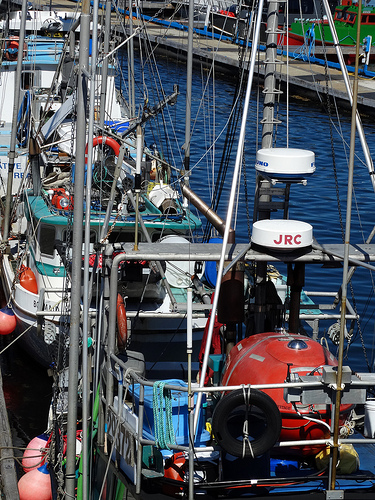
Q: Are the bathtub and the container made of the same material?
A: Yes, both the bathtub and the container are made of plastic.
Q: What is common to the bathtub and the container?
A: The material, both the bathtub and the container are plastic.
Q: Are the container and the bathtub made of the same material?
A: Yes, both the container and the bathtub are made of plastic.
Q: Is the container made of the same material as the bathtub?
A: Yes, both the container and the bathtub are made of plastic.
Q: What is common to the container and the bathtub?
A: The material, both the container and the bathtub are plastic.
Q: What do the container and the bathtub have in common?
A: The material, both the container and the bathtub are plastic.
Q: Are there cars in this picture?
A: No, there are no cars.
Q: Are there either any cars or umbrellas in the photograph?
A: No, there are no cars or umbrellas.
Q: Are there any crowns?
A: No, there are no crowns.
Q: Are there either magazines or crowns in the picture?
A: No, there are no crowns or magazines.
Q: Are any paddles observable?
A: No, there are no paddles.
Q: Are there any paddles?
A: No, there are no paddles.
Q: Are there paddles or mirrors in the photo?
A: No, there are no paddles or mirrors.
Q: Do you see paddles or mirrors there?
A: No, there are no paddles or mirrors.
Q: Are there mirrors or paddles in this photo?
A: No, there are no paddles or mirrors.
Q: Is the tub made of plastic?
A: Yes, the tub is made of plastic.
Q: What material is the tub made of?
A: The tub is made of plastic.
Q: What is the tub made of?
A: The tub is made of plastic.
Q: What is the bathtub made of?
A: The tub is made of plastic.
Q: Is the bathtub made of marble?
A: No, the bathtub is made of plastic.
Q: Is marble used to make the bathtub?
A: No, the bathtub is made of plastic.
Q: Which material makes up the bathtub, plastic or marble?
A: The bathtub is made of plastic.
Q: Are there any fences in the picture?
A: No, there are no fences.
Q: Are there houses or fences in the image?
A: No, there are no fences or houses.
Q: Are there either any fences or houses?
A: No, there are no fences or houses.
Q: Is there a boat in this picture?
A: Yes, there is a boat.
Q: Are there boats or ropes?
A: Yes, there is a boat.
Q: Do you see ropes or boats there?
A: Yes, there is a boat.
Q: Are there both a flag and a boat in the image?
A: No, there is a boat but no flags.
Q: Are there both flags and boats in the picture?
A: No, there is a boat but no flags.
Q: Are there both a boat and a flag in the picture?
A: No, there is a boat but no flags.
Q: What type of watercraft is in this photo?
A: The watercraft is a boat.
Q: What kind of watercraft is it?
A: The watercraft is a boat.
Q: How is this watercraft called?
A: This is a boat.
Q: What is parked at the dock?
A: The boat is parked at the dock.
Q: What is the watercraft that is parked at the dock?
A: The watercraft is a boat.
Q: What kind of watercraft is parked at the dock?
A: The watercraft is a boat.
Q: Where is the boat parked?
A: The boat is parked at the pier.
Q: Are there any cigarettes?
A: No, there are no cigarettes.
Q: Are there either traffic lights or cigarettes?
A: No, there are no cigarettes or traffic lights.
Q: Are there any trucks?
A: No, there are no trucks.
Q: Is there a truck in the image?
A: No, there are no trucks.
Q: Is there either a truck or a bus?
A: No, there are no trucks or buses.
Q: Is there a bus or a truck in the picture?
A: No, there are no trucks or buses.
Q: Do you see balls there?
A: Yes, there is a ball.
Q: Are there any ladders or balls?
A: Yes, there is a ball.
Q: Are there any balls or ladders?
A: Yes, there is a ball.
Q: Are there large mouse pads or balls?
A: Yes, there is a large ball.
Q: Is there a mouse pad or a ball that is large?
A: Yes, the ball is large.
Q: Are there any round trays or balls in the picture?
A: Yes, there is a round ball.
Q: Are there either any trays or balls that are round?
A: Yes, the ball is round.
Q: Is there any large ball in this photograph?
A: Yes, there is a large ball.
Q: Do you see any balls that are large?
A: Yes, there is a ball that is large.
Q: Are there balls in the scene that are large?
A: Yes, there is a ball that is large.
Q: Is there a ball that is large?
A: Yes, there is a ball that is large.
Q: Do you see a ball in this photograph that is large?
A: Yes, there is a ball that is large.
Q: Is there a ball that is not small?
A: Yes, there is a large ball.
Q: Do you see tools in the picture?
A: No, there are no tools.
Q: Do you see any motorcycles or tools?
A: No, there are no tools or motorcycles.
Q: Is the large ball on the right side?
A: Yes, the ball is on the right of the image.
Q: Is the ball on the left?
A: No, the ball is on the right of the image.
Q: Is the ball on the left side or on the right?
A: The ball is on the right of the image.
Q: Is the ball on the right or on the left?
A: The ball is on the right of the image.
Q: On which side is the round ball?
A: The ball is on the right of the image.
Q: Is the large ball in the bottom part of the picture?
A: Yes, the ball is in the bottom of the image.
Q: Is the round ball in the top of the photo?
A: No, the ball is in the bottom of the image.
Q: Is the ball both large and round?
A: Yes, the ball is large and round.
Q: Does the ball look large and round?
A: Yes, the ball is large and round.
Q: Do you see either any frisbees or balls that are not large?
A: No, there is a ball but it is large.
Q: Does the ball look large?
A: Yes, the ball is large.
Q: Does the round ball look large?
A: Yes, the ball is large.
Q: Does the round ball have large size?
A: Yes, the ball is large.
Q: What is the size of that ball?
A: The ball is large.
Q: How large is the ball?
A: The ball is large.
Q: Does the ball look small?
A: No, the ball is large.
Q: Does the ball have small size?
A: No, the ball is large.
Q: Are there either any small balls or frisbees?
A: No, there is a ball but it is large.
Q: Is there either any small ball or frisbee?
A: No, there is a ball but it is large.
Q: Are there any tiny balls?
A: No, there is a ball but it is large.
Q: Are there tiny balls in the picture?
A: No, there is a ball but it is large.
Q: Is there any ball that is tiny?
A: No, there is a ball but it is large.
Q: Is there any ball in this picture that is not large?
A: No, there is a ball but it is large.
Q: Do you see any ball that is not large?
A: No, there is a ball but it is large.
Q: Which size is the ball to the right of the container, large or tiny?
A: The ball is large.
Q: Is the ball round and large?
A: Yes, the ball is round and large.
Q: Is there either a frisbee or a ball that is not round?
A: No, there is a ball but it is round.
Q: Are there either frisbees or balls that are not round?
A: No, there is a ball but it is round.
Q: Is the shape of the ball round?
A: Yes, the ball is round.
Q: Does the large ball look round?
A: Yes, the ball is round.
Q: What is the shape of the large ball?
A: The ball is round.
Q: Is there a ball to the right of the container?
A: Yes, there is a ball to the right of the container.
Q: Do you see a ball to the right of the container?
A: Yes, there is a ball to the right of the container.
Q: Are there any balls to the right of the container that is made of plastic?
A: Yes, there is a ball to the right of the container.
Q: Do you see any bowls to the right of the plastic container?
A: No, there is a ball to the right of the container.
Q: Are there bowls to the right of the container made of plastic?
A: No, there is a ball to the right of the container.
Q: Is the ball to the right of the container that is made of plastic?
A: Yes, the ball is to the right of the container.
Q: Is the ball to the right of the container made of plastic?
A: Yes, the ball is to the right of the container.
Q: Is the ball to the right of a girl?
A: No, the ball is to the right of the container.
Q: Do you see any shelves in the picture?
A: No, there are no shelves.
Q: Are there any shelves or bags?
A: No, there are no shelves or bags.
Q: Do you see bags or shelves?
A: No, there are no shelves or bags.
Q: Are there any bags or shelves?
A: No, there are no shelves or bags.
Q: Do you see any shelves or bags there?
A: No, there are no shelves or bags.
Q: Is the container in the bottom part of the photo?
A: Yes, the container is in the bottom of the image.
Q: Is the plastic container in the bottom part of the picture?
A: Yes, the container is in the bottom of the image.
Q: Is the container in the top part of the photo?
A: No, the container is in the bottom of the image.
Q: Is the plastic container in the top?
A: No, the container is in the bottom of the image.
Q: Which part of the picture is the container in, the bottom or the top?
A: The container is in the bottom of the image.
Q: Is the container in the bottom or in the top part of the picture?
A: The container is in the bottom of the image.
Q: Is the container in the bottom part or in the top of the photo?
A: The container is in the bottom of the image.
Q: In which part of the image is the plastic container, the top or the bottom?
A: The container is in the bottom of the image.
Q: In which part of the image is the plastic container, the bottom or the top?
A: The container is in the bottom of the image.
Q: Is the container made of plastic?
A: Yes, the container is made of plastic.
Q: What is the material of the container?
A: The container is made of plastic.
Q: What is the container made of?
A: The container is made of plastic.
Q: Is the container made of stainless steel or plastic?
A: The container is made of plastic.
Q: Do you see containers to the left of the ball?
A: Yes, there is a container to the left of the ball.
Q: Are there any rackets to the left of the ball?
A: No, there is a container to the left of the ball.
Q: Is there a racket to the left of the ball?
A: No, there is a container to the left of the ball.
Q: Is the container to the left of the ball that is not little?
A: Yes, the container is to the left of the ball.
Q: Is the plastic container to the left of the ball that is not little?
A: Yes, the container is to the left of the ball.